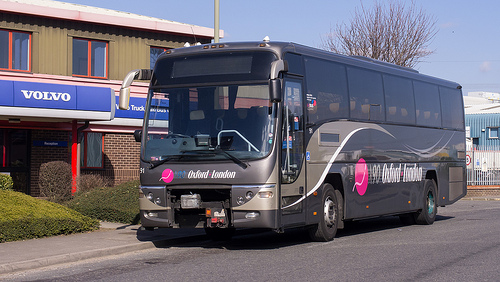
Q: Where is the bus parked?
A: On the pavement.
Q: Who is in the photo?
A: No one.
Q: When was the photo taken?
A: Day time.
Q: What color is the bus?
A: Grey.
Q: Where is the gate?
A: Behind the bus.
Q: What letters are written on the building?
A: Volvo.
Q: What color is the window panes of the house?
A: Red.